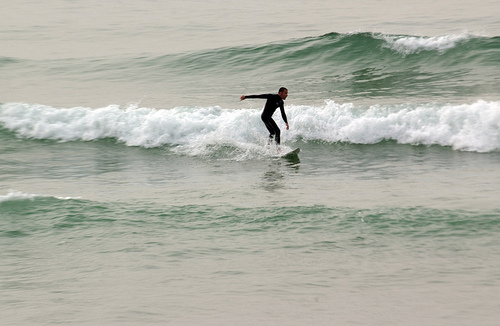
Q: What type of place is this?
A: It is an ocean.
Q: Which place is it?
A: It is an ocean.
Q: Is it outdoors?
A: Yes, it is outdoors.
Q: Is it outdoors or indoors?
A: It is outdoors.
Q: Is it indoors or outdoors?
A: It is outdoors.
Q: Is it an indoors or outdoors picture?
A: It is outdoors.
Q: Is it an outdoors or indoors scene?
A: It is outdoors.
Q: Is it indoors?
A: No, it is outdoors.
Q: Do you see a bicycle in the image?
A: No, there are no bicycles.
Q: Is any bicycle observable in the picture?
A: No, there are no bicycles.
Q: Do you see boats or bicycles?
A: No, there are no bicycles or boats.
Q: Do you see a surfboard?
A: Yes, there is a surfboard.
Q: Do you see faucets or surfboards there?
A: Yes, there is a surfboard.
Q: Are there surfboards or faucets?
A: Yes, there is a surfboard.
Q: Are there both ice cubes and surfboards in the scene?
A: No, there is a surfboard but no ice cubes.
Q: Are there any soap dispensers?
A: No, there are no soap dispensers.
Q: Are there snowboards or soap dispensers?
A: No, there are no soap dispensers or snowboards.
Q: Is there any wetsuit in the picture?
A: Yes, there is a wetsuit.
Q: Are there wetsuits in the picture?
A: Yes, there is a wetsuit.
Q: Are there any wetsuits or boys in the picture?
A: Yes, there is a wetsuit.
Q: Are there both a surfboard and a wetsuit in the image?
A: Yes, there are both a wetsuit and a surfboard.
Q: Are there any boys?
A: No, there are no boys.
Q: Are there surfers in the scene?
A: Yes, there is a surfer.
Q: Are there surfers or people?
A: Yes, there is a surfer.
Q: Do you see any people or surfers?
A: Yes, there is a surfer.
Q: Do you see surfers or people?
A: Yes, there is a surfer.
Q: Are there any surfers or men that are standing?
A: Yes, the surfer is standing.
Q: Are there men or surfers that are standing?
A: Yes, the surfer is standing.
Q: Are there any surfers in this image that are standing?
A: Yes, there is a surfer that is standing.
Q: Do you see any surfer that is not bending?
A: Yes, there is a surfer that is standing .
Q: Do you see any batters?
A: No, there are no batters.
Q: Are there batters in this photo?
A: No, there are no batters.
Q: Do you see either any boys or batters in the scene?
A: No, there are no batters or boys.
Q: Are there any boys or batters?
A: No, there are no batters or boys.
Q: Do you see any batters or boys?
A: No, there are no batters or boys.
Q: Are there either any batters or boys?
A: No, there are no batters or boys.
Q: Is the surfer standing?
A: Yes, the surfer is standing.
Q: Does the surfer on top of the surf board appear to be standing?
A: Yes, the surfer is standing.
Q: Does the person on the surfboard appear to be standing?
A: Yes, the surfer is standing.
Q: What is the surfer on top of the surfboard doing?
A: The surfer is standing.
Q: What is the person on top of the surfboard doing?
A: The surfer is standing.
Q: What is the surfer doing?
A: The surfer is standing.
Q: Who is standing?
A: The surfer is standing.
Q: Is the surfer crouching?
A: No, the surfer is standing.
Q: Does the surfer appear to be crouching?
A: No, the surfer is standing.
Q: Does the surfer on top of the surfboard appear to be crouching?
A: No, the surfer is standing.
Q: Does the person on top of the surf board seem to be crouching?
A: No, the surfer is standing.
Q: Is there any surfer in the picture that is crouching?
A: No, there is a surfer but he is standing.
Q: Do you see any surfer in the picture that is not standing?
A: No, there is a surfer but he is standing.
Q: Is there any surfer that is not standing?
A: No, there is a surfer but he is standing.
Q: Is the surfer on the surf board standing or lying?
A: The surfer is standing.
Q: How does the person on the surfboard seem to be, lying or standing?
A: The surfer is standing.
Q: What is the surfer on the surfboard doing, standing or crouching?
A: The surfer is standing.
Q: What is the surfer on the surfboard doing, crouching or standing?
A: The surfer is standing.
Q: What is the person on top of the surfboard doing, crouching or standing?
A: The surfer is standing.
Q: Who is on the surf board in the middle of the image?
A: The surfer is on the surfboard.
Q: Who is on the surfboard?
A: The surfer is on the surfboard.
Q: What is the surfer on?
A: The surfer is on the surfboard.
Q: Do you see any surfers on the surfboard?
A: Yes, there is a surfer on the surfboard.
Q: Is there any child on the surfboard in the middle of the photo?
A: No, there is a surfer on the surfboard.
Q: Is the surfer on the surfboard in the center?
A: Yes, the surfer is on the surfboard.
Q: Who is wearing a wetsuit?
A: The surfer is wearing a wetsuit.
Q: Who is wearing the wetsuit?
A: The surfer is wearing a wetsuit.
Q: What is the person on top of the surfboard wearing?
A: The surfer is wearing a wetsuit.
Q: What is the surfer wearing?
A: The surfer is wearing a wetsuit.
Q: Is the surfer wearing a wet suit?
A: Yes, the surfer is wearing a wet suit.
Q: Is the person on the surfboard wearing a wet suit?
A: Yes, the surfer is wearing a wet suit.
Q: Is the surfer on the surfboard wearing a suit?
A: No, the surfer is wearing a wet suit.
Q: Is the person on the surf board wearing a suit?
A: No, the surfer is wearing a wet suit.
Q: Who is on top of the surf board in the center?
A: The surfer is on top of the surfboard.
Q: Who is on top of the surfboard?
A: The surfer is on top of the surfboard.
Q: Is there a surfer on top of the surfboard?
A: Yes, there is a surfer on top of the surfboard.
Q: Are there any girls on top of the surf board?
A: No, there is a surfer on top of the surf board.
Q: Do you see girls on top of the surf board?
A: No, there is a surfer on top of the surf board.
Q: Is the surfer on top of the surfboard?
A: Yes, the surfer is on top of the surfboard.